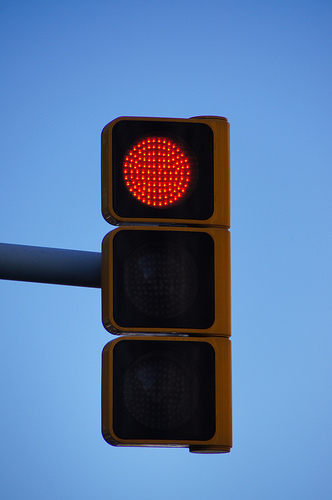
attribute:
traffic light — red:
[100, 117, 228, 226]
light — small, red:
[140, 191, 145, 196]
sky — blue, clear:
[1, 0, 329, 496]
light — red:
[125, 134, 228, 201]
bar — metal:
[0, 240, 100, 285]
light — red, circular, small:
[60, 119, 202, 273]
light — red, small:
[123, 137, 189, 206]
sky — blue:
[214, 38, 301, 115]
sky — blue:
[3, 82, 320, 429]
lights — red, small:
[156, 151, 163, 155]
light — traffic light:
[116, 238, 208, 326]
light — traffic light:
[113, 343, 212, 438]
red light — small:
[125, 133, 191, 207]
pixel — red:
[130, 169, 133, 172]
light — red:
[93, 117, 217, 220]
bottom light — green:
[111, 338, 218, 444]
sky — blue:
[45, 34, 279, 104]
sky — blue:
[17, 6, 321, 102]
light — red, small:
[98, 104, 238, 461]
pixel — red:
[140, 137, 149, 144]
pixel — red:
[184, 170, 190, 174]